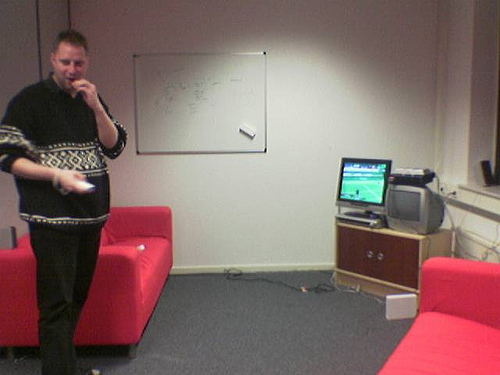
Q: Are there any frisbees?
A: No, there are no frisbees.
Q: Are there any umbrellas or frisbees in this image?
A: No, there are no frisbees or umbrellas.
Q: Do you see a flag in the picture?
A: No, there are no flags.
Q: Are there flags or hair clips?
A: No, there are no flags or hair clips.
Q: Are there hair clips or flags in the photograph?
A: No, there are no flags or hair clips.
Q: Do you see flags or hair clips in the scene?
A: No, there are no flags or hair clips.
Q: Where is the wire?
A: The wire is on the floor.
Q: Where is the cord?
A: The wire is on the floor.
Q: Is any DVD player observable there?
A: No, there are no DVD players.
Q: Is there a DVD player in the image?
A: No, there are no DVD players.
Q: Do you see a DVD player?
A: No, there are no DVD players.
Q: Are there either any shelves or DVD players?
A: No, there are no DVD players or shelves.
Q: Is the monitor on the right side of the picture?
A: Yes, the monitor is on the right of the image.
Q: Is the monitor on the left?
A: No, the monitor is on the right of the image.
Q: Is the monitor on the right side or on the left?
A: The monitor is on the right of the image.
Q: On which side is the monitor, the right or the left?
A: The monitor is on the right of the image.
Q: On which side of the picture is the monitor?
A: The monitor is on the right of the image.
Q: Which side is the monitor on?
A: The monitor is on the right of the image.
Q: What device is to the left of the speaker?
A: The device is a monitor.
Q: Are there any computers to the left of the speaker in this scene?
A: No, there is a monitor to the left of the speaker.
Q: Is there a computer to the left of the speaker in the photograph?
A: No, there is a monitor to the left of the speaker.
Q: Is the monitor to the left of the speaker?
A: Yes, the monitor is to the left of the speaker.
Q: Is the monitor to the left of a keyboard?
A: No, the monitor is to the left of the speaker.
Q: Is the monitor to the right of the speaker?
A: No, the monitor is to the left of the speaker.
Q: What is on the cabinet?
A: The monitor is on the cabinet.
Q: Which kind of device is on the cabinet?
A: The device is a monitor.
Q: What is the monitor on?
A: The monitor is on the cabinet.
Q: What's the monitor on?
A: The monitor is on the cabinet.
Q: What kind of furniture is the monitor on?
A: The monitor is on the cabinet.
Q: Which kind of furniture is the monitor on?
A: The monitor is on the cabinet.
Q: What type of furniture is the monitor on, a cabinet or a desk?
A: The monitor is on a cabinet.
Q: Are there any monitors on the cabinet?
A: Yes, there is a monitor on the cabinet.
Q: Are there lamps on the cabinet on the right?
A: No, there is a monitor on the cabinet.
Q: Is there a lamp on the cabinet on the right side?
A: No, there is a monitor on the cabinet.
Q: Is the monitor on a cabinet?
A: Yes, the monitor is on a cabinet.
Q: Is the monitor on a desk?
A: No, the monitor is on a cabinet.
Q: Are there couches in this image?
A: Yes, there is a couch.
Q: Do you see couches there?
A: Yes, there is a couch.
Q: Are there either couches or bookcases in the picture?
A: Yes, there is a couch.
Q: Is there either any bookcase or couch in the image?
A: Yes, there is a couch.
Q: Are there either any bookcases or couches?
A: Yes, there is a couch.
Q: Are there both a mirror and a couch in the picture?
A: No, there is a couch but no mirrors.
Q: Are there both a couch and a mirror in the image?
A: No, there is a couch but no mirrors.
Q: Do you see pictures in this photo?
A: No, there are no pictures.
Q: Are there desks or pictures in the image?
A: No, there are no pictures or desks.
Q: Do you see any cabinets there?
A: Yes, there is a cabinet.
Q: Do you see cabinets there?
A: Yes, there is a cabinet.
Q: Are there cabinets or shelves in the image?
A: Yes, there is a cabinet.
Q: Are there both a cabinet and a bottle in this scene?
A: No, there is a cabinet but no bottles.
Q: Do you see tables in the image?
A: No, there are no tables.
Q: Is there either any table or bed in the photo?
A: No, there are no tables or beds.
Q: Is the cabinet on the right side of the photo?
A: Yes, the cabinet is on the right of the image.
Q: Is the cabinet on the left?
A: No, the cabinet is on the right of the image.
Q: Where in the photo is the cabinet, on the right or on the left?
A: The cabinet is on the right of the image.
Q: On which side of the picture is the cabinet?
A: The cabinet is on the right of the image.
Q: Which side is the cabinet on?
A: The cabinet is on the right of the image.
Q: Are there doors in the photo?
A: Yes, there is a door.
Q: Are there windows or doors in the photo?
A: Yes, there is a door.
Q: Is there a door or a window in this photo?
A: Yes, there is a door.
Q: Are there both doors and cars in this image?
A: No, there is a door but no cars.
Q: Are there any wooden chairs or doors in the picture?
A: Yes, there is a wood door.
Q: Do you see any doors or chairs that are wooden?
A: Yes, the door is wooden.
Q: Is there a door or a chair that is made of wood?
A: Yes, the door is made of wood.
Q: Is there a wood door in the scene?
A: Yes, there is a wood door.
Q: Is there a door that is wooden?
A: Yes, there is a door that is wooden.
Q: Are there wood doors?
A: Yes, there is a door that is made of wood.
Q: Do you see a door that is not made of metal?
A: Yes, there is a door that is made of wood.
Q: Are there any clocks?
A: No, there are no clocks.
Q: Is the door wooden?
A: Yes, the door is wooden.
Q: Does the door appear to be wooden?
A: Yes, the door is wooden.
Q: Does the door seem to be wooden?
A: Yes, the door is wooden.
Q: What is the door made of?
A: The door is made of wood.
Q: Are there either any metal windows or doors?
A: No, there is a door but it is wooden.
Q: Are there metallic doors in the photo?
A: No, there is a door but it is wooden.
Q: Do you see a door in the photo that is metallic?
A: No, there is a door but it is wooden.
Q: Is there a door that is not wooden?
A: No, there is a door but it is wooden.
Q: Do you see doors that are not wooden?
A: No, there is a door but it is wooden.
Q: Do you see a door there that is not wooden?
A: No, there is a door but it is wooden.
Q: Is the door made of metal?
A: No, the door is made of wood.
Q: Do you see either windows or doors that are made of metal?
A: No, there is a door but it is made of wood.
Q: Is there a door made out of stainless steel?
A: No, there is a door but it is made of wood.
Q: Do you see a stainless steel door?
A: No, there is a door but it is made of wood.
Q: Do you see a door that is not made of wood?
A: No, there is a door but it is made of wood.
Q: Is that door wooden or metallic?
A: The door is wooden.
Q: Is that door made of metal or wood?
A: The door is made of wood.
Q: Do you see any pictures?
A: No, there are no pictures.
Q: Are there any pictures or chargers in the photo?
A: No, there are no pictures or chargers.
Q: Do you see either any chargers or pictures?
A: No, there are no pictures or chargers.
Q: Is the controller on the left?
A: Yes, the controller is on the left of the image.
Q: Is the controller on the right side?
A: No, the controller is on the left of the image.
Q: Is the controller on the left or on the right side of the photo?
A: The controller is on the left of the image.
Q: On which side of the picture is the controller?
A: The controller is on the left of the image.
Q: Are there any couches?
A: Yes, there is a couch.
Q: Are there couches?
A: Yes, there is a couch.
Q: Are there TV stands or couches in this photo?
A: Yes, there is a couch.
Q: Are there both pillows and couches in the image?
A: No, there is a couch but no pillows.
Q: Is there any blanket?
A: No, there are no blankets.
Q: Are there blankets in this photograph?
A: No, there are no blankets.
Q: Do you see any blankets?
A: No, there are no blankets.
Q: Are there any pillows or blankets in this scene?
A: No, there are no blankets or pillows.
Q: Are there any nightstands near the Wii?
A: No, there is a couch near the Wii.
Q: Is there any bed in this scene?
A: No, there are no beds.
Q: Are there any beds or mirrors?
A: No, there are no beds or mirrors.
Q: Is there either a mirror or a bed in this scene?
A: No, there are no beds or mirrors.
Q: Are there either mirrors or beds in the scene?
A: No, there are no beds or mirrors.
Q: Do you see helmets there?
A: No, there are no helmets.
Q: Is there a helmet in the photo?
A: No, there are no helmets.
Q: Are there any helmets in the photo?
A: No, there are no helmets.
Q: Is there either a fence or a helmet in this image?
A: No, there are no helmets or fences.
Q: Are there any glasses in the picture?
A: No, there are no glasses.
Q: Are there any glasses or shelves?
A: No, there are no glasses or shelves.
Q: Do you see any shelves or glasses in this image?
A: No, there are no glasses or shelves.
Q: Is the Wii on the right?
A: Yes, the Wii is on the right of the image.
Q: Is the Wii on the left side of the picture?
A: No, the Wii is on the right of the image.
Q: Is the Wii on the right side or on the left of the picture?
A: The Wii is on the right of the image.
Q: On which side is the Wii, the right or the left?
A: The Wii is on the right of the image.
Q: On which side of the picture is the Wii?
A: The Wii is on the right of the image.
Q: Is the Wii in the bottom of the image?
A: Yes, the Wii is in the bottom of the image.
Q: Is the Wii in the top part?
A: No, the Wii is in the bottom of the image.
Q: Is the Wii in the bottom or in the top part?
A: The Wii is in the bottom of the image.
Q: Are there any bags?
A: No, there are no bags.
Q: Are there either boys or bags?
A: No, there are no bags or boys.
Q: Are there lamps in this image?
A: No, there are no lamps.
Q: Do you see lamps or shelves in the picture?
A: No, there are no lamps or shelves.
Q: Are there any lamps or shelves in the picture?
A: No, there are no lamps or shelves.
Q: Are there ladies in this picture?
A: No, there are no ladies.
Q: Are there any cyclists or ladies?
A: No, there are no ladies or cyclists.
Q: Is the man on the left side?
A: Yes, the man is on the left of the image.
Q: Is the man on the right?
A: No, the man is on the left of the image.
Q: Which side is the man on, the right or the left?
A: The man is on the left of the image.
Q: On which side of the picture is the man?
A: The man is on the left of the image.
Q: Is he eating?
A: Yes, the man is eating.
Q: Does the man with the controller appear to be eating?
A: Yes, the man is eating.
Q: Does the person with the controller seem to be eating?
A: Yes, the man is eating.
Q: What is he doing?
A: The man is eating.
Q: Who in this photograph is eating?
A: The man is eating.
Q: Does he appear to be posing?
A: No, the man is eating.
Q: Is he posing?
A: No, the man is eating.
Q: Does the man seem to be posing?
A: No, the man is eating.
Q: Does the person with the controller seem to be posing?
A: No, the man is eating.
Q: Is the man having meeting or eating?
A: The man is eating.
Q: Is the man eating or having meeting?
A: The man is eating.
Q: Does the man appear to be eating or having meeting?
A: The man is eating.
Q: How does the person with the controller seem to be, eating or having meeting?
A: The man is eating.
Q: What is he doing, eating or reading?
A: The man is eating.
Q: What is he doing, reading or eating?
A: The man is eating.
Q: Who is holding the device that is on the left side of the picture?
A: The man is holding the controller.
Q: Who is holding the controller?
A: The man is holding the controller.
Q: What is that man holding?
A: The man is holding the controller.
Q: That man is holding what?
A: The man is holding the controller.